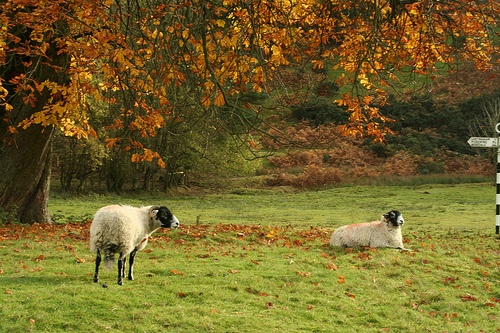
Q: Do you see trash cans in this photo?
A: No, there are no trash cans.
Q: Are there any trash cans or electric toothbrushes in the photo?
A: No, there are no trash cans or electric toothbrushes.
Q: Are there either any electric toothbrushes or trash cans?
A: No, there are no trash cans or electric toothbrushes.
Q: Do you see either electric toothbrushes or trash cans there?
A: No, there are no trash cans or electric toothbrushes.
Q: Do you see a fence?
A: No, there are no fences.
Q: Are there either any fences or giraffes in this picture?
A: No, there are no fences or giraffes.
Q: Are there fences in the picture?
A: No, there are no fences.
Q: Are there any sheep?
A: Yes, there is a sheep.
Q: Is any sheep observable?
A: Yes, there is a sheep.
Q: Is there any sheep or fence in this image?
A: Yes, there is a sheep.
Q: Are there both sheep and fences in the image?
A: No, there is a sheep but no fences.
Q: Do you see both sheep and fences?
A: No, there is a sheep but no fences.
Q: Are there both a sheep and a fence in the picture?
A: No, there is a sheep but no fences.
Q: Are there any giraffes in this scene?
A: No, there are no giraffes.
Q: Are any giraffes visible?
A: No, there are no giraffes.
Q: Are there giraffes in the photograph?
A: No, there are no giraffes.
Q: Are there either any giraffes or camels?
A: No, there are no giraffes or camels.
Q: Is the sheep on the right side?
A: Yes, the sheep is on the right of the image.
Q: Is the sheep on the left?
A: No, the sheep is on the right of the image.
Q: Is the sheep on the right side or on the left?
A: The sheep is on the right of the image.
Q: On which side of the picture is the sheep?
A: The sheep is on the right of the image.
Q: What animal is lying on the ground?
A: The sheep is lying on the ground.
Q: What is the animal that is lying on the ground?
A: The animal is a sheep.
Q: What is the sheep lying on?
A: The sheep is lying on the ground.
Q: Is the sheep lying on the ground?
A: Yes, the sheep is lying on the ground.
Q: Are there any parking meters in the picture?
A: No, there are no parking meters.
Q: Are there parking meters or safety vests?
A: No, there are no parking meters or safety vests.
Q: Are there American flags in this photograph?
A: No, there are no American flags.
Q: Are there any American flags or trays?
A: No, there are no American flags or trays.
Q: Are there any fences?
A: No, there are no fences.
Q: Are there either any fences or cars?
A: No, there are no fences or cars.